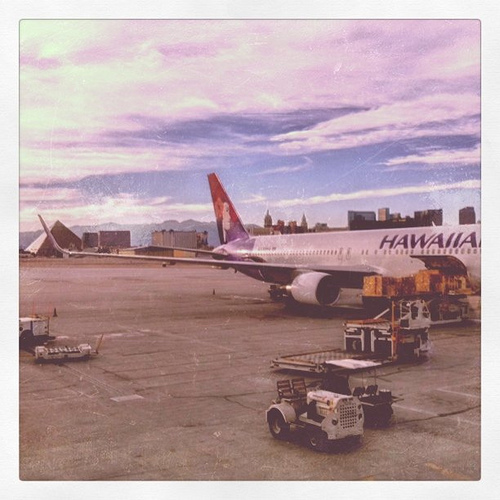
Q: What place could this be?
A: It is an airport.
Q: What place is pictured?
A: It is an airport.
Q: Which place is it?
A: It is an airport.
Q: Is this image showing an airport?
A: Yes, it is showing an airport.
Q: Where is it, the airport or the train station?
A: It is the airport.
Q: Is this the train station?
A: No, it is the airport.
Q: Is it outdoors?
A: Yes, it is outdoors.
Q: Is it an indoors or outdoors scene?
A: It is outdoors.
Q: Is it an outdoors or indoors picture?
A: It is outdoors.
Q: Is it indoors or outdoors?
A: It is outdoors.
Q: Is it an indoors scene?
A: No, it is outdoors.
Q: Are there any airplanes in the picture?
A: Yes, there is an airplane.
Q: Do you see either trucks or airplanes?
A: Yes, there is an airplane.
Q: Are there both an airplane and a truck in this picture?
A: Yes, there are both an airplane and a truck.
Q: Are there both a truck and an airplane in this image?
A: Yes, there are both an airplane and a truck.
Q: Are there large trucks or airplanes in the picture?
A: Yes, there is a large airplane.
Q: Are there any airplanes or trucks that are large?
A: Yes, the airplane is large.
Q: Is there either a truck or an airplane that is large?
A: Yes, the airplane is large.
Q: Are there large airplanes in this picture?
A: Yes, there is a large airplane.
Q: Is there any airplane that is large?
A: Yes, there is an airplane that is large.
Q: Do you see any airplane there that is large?
A: Yes, there is an airplane that is large.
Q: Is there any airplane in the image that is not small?
A: Yes, there is a large airplane.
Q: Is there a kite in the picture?
A: No, there are no kites.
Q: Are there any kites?
A: No, there are no kites.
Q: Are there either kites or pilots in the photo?
A: No, there are no kites or pilots.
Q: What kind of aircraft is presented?
A: The aircraft is an airplane.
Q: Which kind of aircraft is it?
A: The aircraft is an airplane.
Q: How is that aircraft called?
A: This is an airplane.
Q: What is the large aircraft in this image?
A: The aircraft is an airplane.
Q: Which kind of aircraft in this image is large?
A: The aircraft is an airplane.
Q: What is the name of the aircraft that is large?
A: The aircraft is an airplane.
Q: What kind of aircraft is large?
A: The aircraft is an airplane.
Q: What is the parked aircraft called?
A: The aircraft is an airplane.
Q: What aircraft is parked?
A: The aircraft is an airplane.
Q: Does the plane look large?
A: Yes, the plane is large.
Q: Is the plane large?
A: Yes, the plane is large.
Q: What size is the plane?
A: The plane is large.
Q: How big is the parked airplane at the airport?
A: The plane is large.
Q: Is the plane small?
A: No, the plane is large.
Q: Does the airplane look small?
A: No, the airplane is large.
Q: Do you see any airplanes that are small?
A: No, there is an airplane but it is large.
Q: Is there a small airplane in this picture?
A: No, there is an airplane but it is large.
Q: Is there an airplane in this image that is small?
A: No, there is an airplane but it is large.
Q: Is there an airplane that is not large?
A: No, there is an airplane but it is large.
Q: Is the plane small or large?
A: The plane is large.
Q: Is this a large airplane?
A: Yes, this is a large airplane.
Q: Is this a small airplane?
A: No, this is a large airplane.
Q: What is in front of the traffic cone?
A: The plane is in front of the traffic cone.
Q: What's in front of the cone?
A: The plane is in front of the traffic cone.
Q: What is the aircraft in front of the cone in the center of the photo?
A: The aircraft is an airplane.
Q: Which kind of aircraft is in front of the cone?
A: The aircraft is an airplane.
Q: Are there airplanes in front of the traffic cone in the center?
A: Yes, there is an airplane in front of the safety cone.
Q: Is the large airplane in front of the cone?
A: Yes, the plane is in front of the cone.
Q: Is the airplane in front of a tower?
A: No, the airplane is in front of the cone.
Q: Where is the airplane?
A: The airplane is at the airport.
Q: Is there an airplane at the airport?
A: Yes, there is an airplane at the airport.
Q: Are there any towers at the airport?
A: No, there is an airplane at the airport.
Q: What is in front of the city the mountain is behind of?
A: The airplane is in front of the city.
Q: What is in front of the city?
A: The airplane is in front of the city.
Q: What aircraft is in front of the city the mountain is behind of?
A: The aircraft is an airplane.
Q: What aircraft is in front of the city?
A: The aircraft is an airplane.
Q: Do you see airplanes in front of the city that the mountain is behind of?
A: Yes, there is an airplane in front of the city.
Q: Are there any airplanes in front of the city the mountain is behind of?
A: Yes, there is an airplane in front of the city.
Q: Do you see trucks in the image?
A: Yes, there is a truck.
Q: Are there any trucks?
A: Yes, there is a truck.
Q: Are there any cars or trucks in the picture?
A: Yes, there is a truck.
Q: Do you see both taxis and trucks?
A: No, there is a truck but no taxis.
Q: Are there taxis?
A: No, there are no taxis.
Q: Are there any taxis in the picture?
A: No, there are no taxis.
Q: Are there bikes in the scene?
A: No, there are no bikes.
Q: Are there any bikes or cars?
A: No, there are no bikes or cars.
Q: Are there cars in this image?
A: No, there are no cars.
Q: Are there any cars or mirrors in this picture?
A: No, there are no cars or mirrors.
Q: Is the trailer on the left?
A: Yes, the trailer is on the left of the image.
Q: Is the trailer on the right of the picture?
A: No, the trailer is on the left of the image.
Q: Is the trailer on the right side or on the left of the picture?
A: The trailer is on the left of the image.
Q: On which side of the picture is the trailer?
A: The trailer is on the left of the image.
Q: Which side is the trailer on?
A: The trailer is on the left of the image.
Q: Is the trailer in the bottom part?
A: Yes, the trailer is in the bottom of the image.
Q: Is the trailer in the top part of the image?
A: No, the trailer is in the bottom of the image.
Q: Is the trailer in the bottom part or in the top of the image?
A: The trailer is in the bottom of the image.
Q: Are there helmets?
A: No, there are no helmets.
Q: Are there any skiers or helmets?
A: No, there are no helmets or skiers.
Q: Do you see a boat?
A: No, there are no boats.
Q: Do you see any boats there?
A: No, there are no boats.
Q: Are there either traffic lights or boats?
A: No, there are no boats or traffic lights.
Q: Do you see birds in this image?
A: No, there are no birds.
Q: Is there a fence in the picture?
A: No, there are no fences.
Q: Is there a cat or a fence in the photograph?
A: No, there are no fences or cats.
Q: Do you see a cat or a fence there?
A: No, there are no fences or cats.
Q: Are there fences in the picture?
A: No, there are no fences.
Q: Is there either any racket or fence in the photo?
A: No, there are no fences or rackets.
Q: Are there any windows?
A: Yes, there are windows.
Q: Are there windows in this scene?
A: Yes, there are windows.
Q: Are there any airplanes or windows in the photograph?
A: Yes, there are windows.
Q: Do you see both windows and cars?
A: No, there are windows but no cars.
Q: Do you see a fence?
A: No, there are no fences.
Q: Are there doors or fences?
A: No, there are no fences or doors.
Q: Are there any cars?
A: No, there are no cars.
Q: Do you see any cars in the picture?
A: No, there are no cars.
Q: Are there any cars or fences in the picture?
A: No, there are no cars or fences.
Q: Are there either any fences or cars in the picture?
A: No, there are no cars or fences.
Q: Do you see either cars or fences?
A: No, there are no cars or fences.